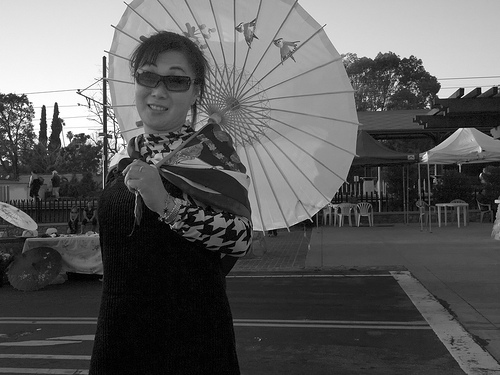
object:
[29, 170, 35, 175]
face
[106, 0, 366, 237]
umbrella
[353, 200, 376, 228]
chair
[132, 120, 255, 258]
shirt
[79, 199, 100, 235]
person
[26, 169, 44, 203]
person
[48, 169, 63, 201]
person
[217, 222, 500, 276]
sidewalk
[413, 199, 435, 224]
chair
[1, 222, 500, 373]
ground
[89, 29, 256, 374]
woman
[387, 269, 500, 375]
paint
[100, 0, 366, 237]
parasol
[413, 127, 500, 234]
canopies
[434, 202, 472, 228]
tables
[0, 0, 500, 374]
photo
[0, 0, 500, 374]
downtown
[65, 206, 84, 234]
person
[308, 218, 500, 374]
side walk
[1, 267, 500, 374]
street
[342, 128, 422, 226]
umbrella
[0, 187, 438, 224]
fence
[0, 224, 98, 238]
wall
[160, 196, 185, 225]
bracelets